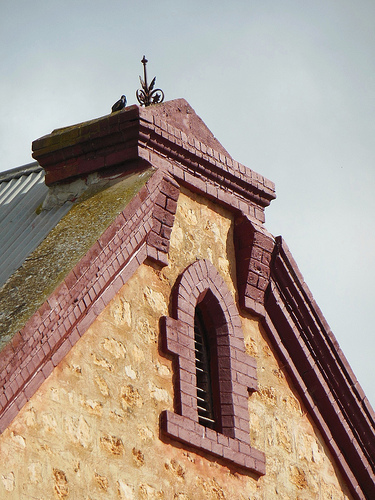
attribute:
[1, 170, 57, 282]
roofing material — metal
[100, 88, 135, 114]
bird — resting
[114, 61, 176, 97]
rod — pointy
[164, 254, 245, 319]
arch — architctural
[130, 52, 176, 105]
decoration — pointy, round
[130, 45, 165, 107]
decorative — trim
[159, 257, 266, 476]
frame — large, bricked, arched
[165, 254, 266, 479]
window framing — red brick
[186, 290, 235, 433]
window — large, brick, framed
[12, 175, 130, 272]
moss — growing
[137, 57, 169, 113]
decoration — scrolled , iron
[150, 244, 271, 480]
window frame — brick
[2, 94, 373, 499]
building — unique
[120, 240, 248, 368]
front — beige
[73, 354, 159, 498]
stone — brown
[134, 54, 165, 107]
lightning rod — decorative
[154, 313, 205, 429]
trim — red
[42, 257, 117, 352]
trim — red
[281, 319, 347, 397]
trim — red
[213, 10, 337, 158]
sky — clear, greyish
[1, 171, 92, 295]
roof — metal, gray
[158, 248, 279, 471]
window — arched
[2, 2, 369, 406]
sky — pale blue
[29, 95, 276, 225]
rooftop — red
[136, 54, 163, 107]
decoration — metal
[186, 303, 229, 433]
window — dark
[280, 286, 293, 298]
brick — red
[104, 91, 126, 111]
bird — black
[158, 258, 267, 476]
area — large, red, arched, brick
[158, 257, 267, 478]
brick — arched, red